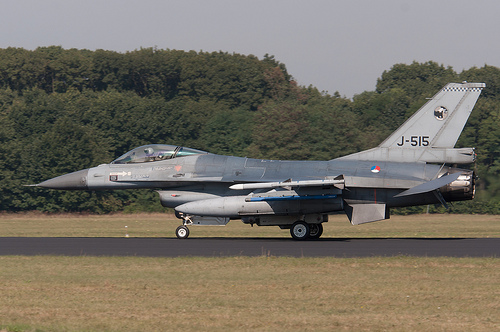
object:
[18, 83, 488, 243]
plane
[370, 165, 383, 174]
circle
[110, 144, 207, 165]
cockpit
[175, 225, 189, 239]
front wheel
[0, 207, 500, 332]
ground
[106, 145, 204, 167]
top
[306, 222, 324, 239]
wheel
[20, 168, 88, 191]
nose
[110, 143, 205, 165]
part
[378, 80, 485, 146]
part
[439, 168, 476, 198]
part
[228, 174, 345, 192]
part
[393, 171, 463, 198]
fins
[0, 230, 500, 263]
runway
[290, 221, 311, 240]
rear wheels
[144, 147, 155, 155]
helmet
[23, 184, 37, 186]
front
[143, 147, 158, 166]
pilot